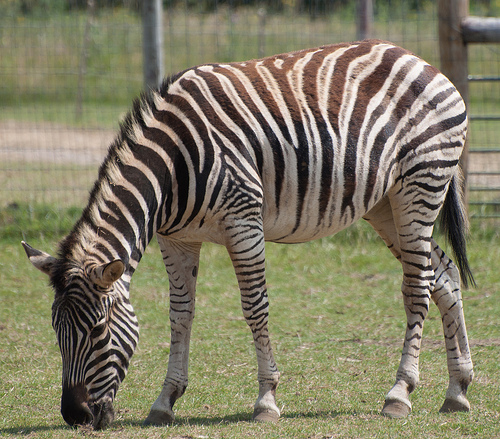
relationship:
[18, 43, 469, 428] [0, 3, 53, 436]
zebra in fenced area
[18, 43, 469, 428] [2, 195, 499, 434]
zebra grazing in grass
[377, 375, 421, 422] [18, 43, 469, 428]
back hoove of zebra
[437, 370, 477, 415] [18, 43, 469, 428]
back hoove of zebra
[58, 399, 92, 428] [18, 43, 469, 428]
nose of zebra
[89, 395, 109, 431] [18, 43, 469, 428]
mouth of zebra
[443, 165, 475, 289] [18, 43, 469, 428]
tail of zebra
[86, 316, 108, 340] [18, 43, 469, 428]
left eye of zebra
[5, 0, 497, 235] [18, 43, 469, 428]
fence behind zebra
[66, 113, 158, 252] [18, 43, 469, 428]
mane on zebra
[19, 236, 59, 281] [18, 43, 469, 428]
ear of zebra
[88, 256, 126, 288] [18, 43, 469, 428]
ear of zebra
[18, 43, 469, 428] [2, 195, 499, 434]
zebra eating grass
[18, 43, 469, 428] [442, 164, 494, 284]
zebra has tail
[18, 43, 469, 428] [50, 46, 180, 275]
zebra has hair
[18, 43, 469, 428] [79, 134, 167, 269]
zebra has neck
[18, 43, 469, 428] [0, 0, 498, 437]
zebra on grass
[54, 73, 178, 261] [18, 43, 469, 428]
mane on zebra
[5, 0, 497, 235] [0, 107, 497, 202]
fence on road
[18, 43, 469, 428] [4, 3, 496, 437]
zebra belongs to zoo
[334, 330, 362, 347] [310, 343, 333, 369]
dirt between grass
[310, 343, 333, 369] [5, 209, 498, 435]
grass on ground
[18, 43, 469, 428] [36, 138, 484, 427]
zebra out in sunshine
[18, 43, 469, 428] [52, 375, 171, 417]
zebra watching for danger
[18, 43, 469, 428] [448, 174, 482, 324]
zebra has a tail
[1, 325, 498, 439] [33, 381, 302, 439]
ground consist of grass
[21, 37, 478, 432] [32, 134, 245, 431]
zebra has brown hooves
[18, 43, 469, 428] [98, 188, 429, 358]
zebra grazing in enclosure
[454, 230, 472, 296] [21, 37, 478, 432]
haired tail on zebra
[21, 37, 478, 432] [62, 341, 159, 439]
zebra mouth grazing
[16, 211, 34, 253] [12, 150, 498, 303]
rails on gate